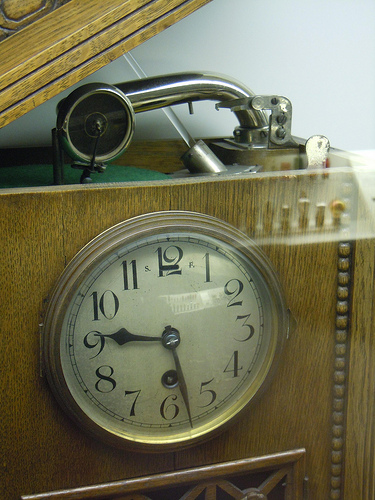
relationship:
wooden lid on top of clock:
[0, 1, 219, 127] [36, 205, 285, 456]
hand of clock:
[169, 345, 199, 431] [36, 205, 285, 456]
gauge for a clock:
[53, 81, 137, 164] [36, 205, 285, 456]